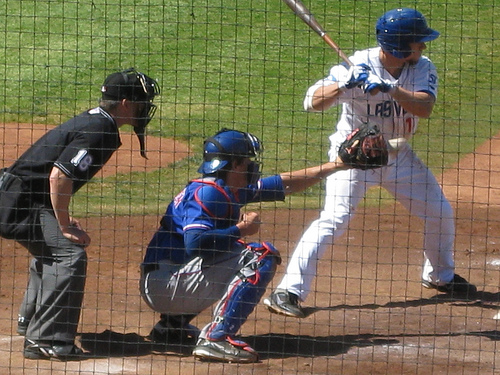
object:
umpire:
[0, 68, 162, 360]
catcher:
[139, 126, 391, 363]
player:
[262, 0, 477, 318]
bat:
[275, 0, 380, 95]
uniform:
[0, 108, 124, 345]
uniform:
[274, 45, 456, 300]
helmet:
[375, 5, 440, 58]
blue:
[395, 15, 414, 28]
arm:
[259, 160, 352, 202]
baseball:
[264, 0, 476, 317]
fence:
[0, 1, 500, 374]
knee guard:
[201, 232, 283, 362]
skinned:
[401, 92, 428, 106]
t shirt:
[0, 112, 123, 238]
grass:
[0, 0, 500, 219]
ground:
[185, 42, 279, 94]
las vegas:
[364, 96, 409, 116]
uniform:
[139, 173, 287, 353]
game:
[262, 1, 477, 317]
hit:
[288, 0, 378, 98]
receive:
[339, 124, 392, 170]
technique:
[302, 45, 449, 118]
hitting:
[333, 48, 384, 97]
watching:
[141, 85, 158, 120]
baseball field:
[0, 0, 500, 374]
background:
[0, 0, 500, 217]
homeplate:
[361, 332, 431, 367]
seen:
[392, 345, 414, 356]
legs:
[310, 198, 351, 227]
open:
[345, 202, 432, 285]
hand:
[59, 221, 93, 250]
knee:
[69, 249, 88, 270]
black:
[355, 141, 369, 160]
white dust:
[486, 257, 500, 270]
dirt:
[469, 200, 497, 227]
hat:
[198, 129, 265, 175]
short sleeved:
[414, 75, 438, 103]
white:
[348, 107, 361, 120]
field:
[0, 2, 500, 217]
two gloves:
[333, 60, 396, 97]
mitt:
[336, 123, 391, 171]